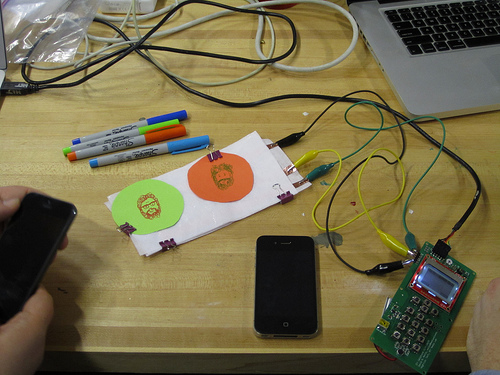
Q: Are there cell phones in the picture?
A: Yes, there is a cell phone.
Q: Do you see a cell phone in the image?
A: Yes, there is a cell phone.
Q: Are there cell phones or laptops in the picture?
A: Yes, there is a cell phone.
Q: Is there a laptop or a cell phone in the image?
A: Yes, there is a cell phone.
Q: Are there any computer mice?
A: No, there are no computer mice.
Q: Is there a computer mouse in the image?
A: No, there are no computer mice.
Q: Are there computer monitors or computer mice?
A: No, there are no computer mice or computer monitors.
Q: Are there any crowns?
A: No, there are no crowns.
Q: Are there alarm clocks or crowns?
A: No, there are no crowns or alarm clocks.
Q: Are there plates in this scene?
A: No, there are no plates.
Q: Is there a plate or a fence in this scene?
A: No, there are no plates or fences.